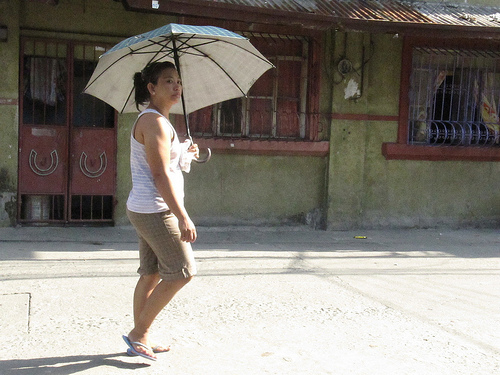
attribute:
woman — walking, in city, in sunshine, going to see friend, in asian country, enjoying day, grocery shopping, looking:
[120, 60, 203, 365]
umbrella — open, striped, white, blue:
[79, 22, 279, 166]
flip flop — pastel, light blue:
[118, 334, 160, 362]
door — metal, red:
[16, 36, 120, 231]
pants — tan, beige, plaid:
[124, 202, 200, 281]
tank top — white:
[123, 108, 185, 217]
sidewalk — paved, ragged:
[1, 227, 500, 375]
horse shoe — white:
[77, 149, 109, 180]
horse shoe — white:
[28, 148, 58, 175]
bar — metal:
[442, 54, 462, 144]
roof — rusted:
[138, 0, 499, 38]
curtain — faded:
[408, 52, 499, 143]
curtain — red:
[23, 56, 69, 107]